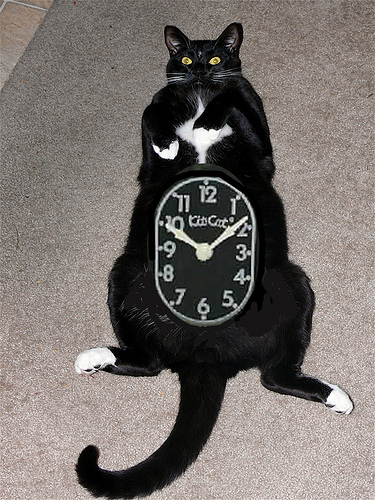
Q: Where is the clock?
A: On the cat.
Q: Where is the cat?
A: On carpet.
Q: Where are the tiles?
A: Next to carpet.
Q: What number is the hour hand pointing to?
A: 10.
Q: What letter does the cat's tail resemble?
A: J.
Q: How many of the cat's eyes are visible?
A: 2.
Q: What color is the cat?
A: Black and white.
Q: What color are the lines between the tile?
A: White.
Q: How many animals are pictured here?
A: One.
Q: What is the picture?
A: Clock.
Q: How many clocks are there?
A: One.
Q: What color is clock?
A: Black and white.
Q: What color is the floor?
A: Grey.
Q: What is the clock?
A: Cat.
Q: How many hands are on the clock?
A: Two.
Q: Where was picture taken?
A: Above a cat.